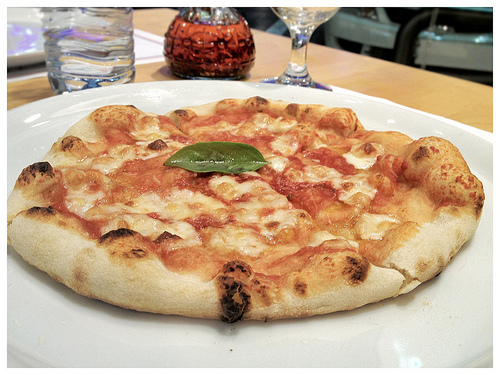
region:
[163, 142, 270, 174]
Basil is on the pizza.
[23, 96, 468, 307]
The pizza has cheese.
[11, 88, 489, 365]
The plate is white.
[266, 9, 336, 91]
A glass is by the plate.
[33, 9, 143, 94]
A water bottle is visible.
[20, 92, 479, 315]
The pizza is cut.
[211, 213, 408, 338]
Section of the pizza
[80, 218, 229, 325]
Section of the pizza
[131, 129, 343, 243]
Section of the pizza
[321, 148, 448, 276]
Section of the pizza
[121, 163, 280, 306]
Section of the pizza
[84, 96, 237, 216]
Section of the pizza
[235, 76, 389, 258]
Section of the pizza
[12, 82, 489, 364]
small pizza on large white plate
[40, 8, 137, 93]
clear container with wavy glass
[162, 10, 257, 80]
round textured bottle with amber liquid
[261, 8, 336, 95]
clear stemmed glass behind plate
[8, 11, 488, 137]
wooden table under plate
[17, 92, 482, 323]
green basil leaf in middle of pie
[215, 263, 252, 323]
burst black bubble of crust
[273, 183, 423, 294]
cut separating two slices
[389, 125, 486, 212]
large bubbles on crust with sauce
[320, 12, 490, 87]
tops of chairs near table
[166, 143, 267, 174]
the bayleaf in the middle of the pizza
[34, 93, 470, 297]
the pizza is all cheese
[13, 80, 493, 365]
the white plate is round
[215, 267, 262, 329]
the crust is burned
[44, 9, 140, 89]
the bottle of water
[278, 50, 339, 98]
the wine glass is clear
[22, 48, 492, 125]
the table is light wood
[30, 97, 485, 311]
the pizza is cut in 6 slices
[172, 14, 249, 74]
the dark liquid behind the pizza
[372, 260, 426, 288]
the crust has a crack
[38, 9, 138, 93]
part of a bottled water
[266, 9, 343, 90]
part of glass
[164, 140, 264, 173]
a green leaf on the top of pizza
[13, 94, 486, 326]
a whole, uneaten pizza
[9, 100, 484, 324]
a whole cheese pizza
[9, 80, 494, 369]
a white plate with pizza on it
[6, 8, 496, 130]
part of tan colored table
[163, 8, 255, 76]
red goblet on the table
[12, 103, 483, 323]
a delicious cheese pizza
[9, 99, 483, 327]
a tasty cheese pizza on a white plate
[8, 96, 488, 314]
A pizza on a white plate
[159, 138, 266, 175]
A bay leaf on a pizza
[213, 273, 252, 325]
A burned section of crust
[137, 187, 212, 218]
Melted cheese on a pizza